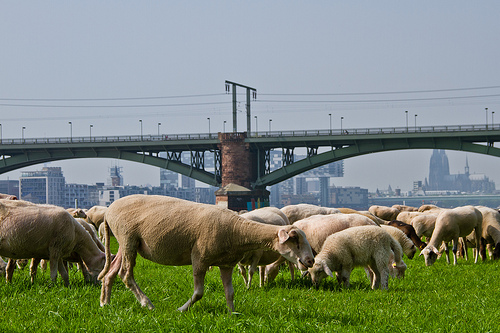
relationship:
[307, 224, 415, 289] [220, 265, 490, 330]
animal in field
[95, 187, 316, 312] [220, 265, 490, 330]
animal in field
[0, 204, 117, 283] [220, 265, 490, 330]
animal in field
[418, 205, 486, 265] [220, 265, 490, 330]
animal in field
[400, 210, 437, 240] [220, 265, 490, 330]
sheep in field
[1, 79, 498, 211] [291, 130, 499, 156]
bridge with support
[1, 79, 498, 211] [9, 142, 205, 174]
bridge with support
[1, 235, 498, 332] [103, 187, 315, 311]
grass under animal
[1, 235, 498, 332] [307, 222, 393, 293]
grass under animal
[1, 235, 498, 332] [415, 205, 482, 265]
grass under animal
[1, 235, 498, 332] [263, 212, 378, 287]
grass under animal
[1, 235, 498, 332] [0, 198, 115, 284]
grass under animal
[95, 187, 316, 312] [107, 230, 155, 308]
animal has leg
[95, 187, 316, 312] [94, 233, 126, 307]
animal has leg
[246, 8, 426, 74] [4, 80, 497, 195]
sky above bridge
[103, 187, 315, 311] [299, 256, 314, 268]
animal has nose